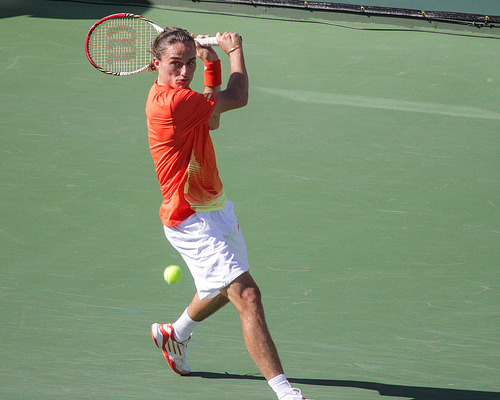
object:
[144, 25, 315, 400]
man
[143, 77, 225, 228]
shirt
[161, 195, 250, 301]
shorts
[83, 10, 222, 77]
racket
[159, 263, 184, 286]
ball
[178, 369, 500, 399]
shadow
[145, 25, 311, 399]
female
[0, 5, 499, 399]
court